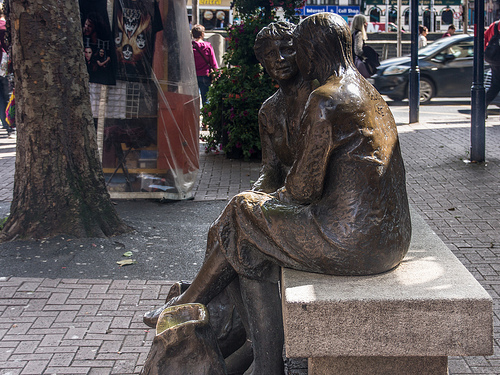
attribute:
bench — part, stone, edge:
[384, 292, 428, 318]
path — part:
[438, 143, 457, 157]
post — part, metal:
[476, 46, 487, 56]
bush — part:
[228, 84, 240, 94]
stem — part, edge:
[246, 11, 265, 18]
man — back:
[269, 1, 405, 289]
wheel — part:
[422, 78, 440, 102]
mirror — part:
[436, 51, 462, 63]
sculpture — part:
[351, 105, 382, 138]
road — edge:
[434, 107, 444, 111]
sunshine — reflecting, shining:
[317, 10, 357, 31]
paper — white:
[154, 179, 175, 189]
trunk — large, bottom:
[36, 215, 126, 233]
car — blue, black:
[369, 40, 462, 100]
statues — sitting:
[258, 63, 352, 188]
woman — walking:
[183, 24, 217, 137]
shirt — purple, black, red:
[197, 64, 207, 77]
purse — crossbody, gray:
[192, 43, 219, 74]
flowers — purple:
[237, 110, 254, 150]